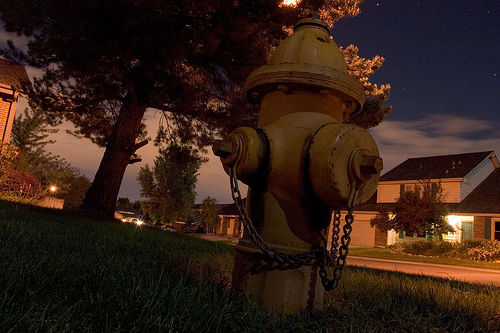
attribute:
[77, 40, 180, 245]
tree — big, close, far, long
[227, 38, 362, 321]
hydrant — sitting, solid, close, yellow, bright, fire, small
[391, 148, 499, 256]
house — big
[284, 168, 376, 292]
chain — silver, hanging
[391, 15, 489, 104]
sky — blue, dark, black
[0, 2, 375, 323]
tree — big, shadowy